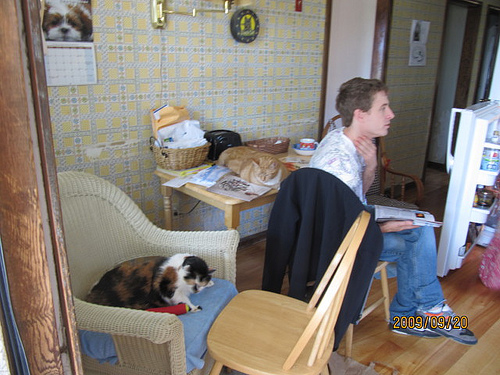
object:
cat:
[83, 252, 216, 313]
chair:
[46, 169, 241, 374]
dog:
[40, 0, 94, 42]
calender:
[26, 0, 95, 88]